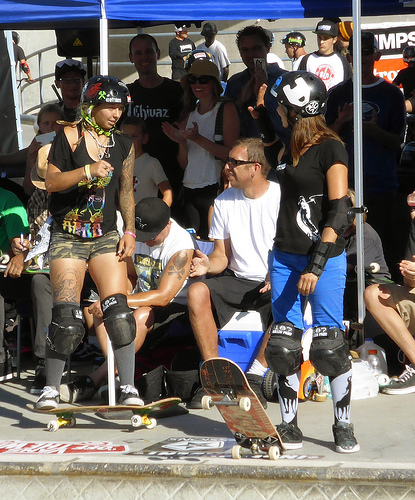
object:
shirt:
[1, 188, 32, 257]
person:
[0, 189, 33, 326]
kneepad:
[307, 327, 353, 380]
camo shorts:
[48, 230, 124, 263]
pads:
[324, 192, 357, 237]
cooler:
[199, 308, 278, 386]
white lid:
[222, 308, 267, 333]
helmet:
[81, 72, 133, 108]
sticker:
[98, 88, 107, 100]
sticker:
[82, 80, 102, 99]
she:
[37, 74, 147, 410]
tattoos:
[118, 140, 139, 234]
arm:
[119, 135, 138, 230]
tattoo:
[51, 269, 80, 304]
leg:
[45, 232, 84, 391]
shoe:
[380, 366, 415, 394]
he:
[186, 136, 282, 411]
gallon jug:
[356, 336, 389, 382]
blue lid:
[365, 335, 371, 342]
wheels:
[199, 394, 214, 412]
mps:
[376, 28, 415, 53]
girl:
[263, 71, 361, 454]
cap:
[311, 18, 341, 39]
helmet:
[271, 68, 329, 118]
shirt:
[273, 130, 347, 259]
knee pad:
[98, 293, 137, 349]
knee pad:
[46, 300, 87, 363]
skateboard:
[198, 355, 288, 460]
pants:
[267, 243, 348, 328]